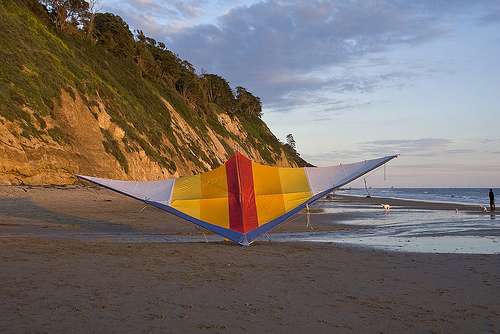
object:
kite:
[74, 148, 399, 246]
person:
[488, 186, 498, 213]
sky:
[237, 0, 500, 122]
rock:
[102, 198, 112, 202]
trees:
[234, 84, 264, 114]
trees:
[283, 133, 301, 150]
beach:
[0, 199, 500, 333]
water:
[421, 186, 500, 203]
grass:
[1, 50, 108, 88]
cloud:
[163, 0, 470, 113]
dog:
[379, 202, 392, 214]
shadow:
[1, 194, 141, 237]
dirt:
[1, 120, 100, 170]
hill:
[0, 0, 317, 188]